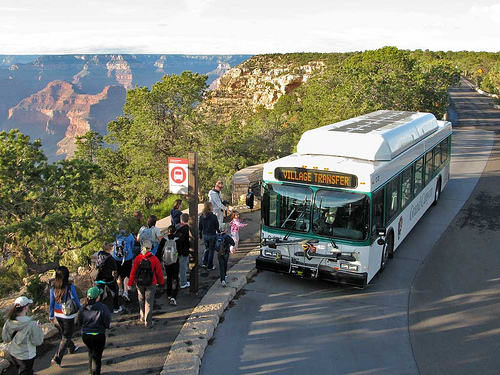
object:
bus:
[244, 109, 453, 291]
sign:
[167, 156, 188, 194]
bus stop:
[102, 150, 261, 296]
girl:
[229, 210, 249, 254]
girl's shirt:
[230, 218, 246, 233]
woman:
[127, 239, 167, 329]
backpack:
[135, 253, 155, 286]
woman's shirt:
[116, 235, 135, 259]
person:
[0, 294, 46, 375]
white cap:
[13, 296, 34, 308]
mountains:
[0, 78, 127, 164]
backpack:
[162, 237, 180, 266]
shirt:
[45, 284, 82, 320]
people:
[94, 239, 123, 314]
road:
[196, 73, 500, 375]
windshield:
[263, 182, 371, 242]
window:
[387, 174, 401, 226]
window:
[401, 164, 414, 213]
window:
[414, 155, 424, 198]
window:
[425, 149, 433, 185]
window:
[434, 142, 442, 170]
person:
[76, 285, 112, 375]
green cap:
[87, 286, 104, 300]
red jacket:
[126, 251, 165, 286]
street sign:
[477, 68, 483, 74]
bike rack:
[261, 235, 357, 279]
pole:
[187, 152, 201, 295]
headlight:
[340, 263, 359, 271]